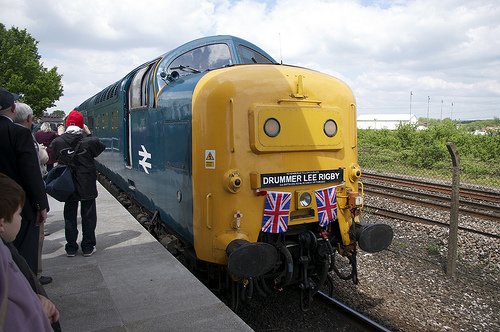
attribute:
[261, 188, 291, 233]
flag — british, english, red, white, blue, small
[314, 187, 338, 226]
flag — british, english, red, white, blue, small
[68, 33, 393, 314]
train — blue, yellow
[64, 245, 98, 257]
shoes — blue, white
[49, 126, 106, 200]
jacket — black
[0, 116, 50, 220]
jacket — black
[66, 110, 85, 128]
hat — red, knitted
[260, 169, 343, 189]
name sign — white, black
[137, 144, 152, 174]
logo — white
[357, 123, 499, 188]
bushes — small, green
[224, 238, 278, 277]
speaker — black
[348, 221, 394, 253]
speaker — black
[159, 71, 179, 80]
horn — blue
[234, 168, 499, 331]
gravel — brown, white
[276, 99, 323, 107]
handle — yellow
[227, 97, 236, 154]
handle — yellow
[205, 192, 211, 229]
handle — yellow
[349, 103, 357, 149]
handle — yellow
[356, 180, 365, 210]
handle — yellow